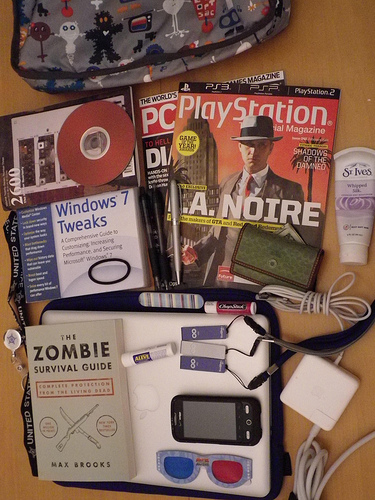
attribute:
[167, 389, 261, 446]
phone — black, cell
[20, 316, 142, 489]
book — gray colored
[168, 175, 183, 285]
pen — pictured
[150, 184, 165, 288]
pen — pictured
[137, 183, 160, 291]
pen — pictured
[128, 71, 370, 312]
magazines — video game, wooden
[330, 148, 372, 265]
bottle — small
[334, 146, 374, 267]
lotion — St. Ives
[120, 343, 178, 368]
white tube — small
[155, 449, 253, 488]
glasses — 3-d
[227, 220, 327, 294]
wallet — green, leather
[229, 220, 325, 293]
clutch — green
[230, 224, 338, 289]
trim — brown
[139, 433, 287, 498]
glasses — red, blue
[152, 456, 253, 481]
glasses — blue, red, 3-D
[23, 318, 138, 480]
paperback book — light brown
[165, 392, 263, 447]
cell phone — small, black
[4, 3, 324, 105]
bag — gray, wooden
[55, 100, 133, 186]
cd — red, round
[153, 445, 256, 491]
3d glasses — red, blue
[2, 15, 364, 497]
table — brown